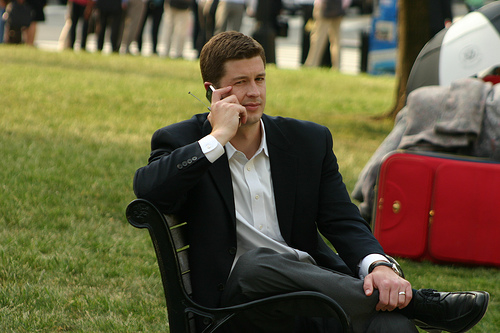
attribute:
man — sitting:
[130, 25, 494, 332]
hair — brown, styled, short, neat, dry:
[193, 28, 272, 89]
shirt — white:
[197, 110, 317, 285]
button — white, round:
[246, 166, 257, 175]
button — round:
[253, 192, 261, 202]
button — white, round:
[255, 220, 266, 232]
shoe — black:
[414, 282, 491, 332]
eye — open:
[254, 73, 266, 85]